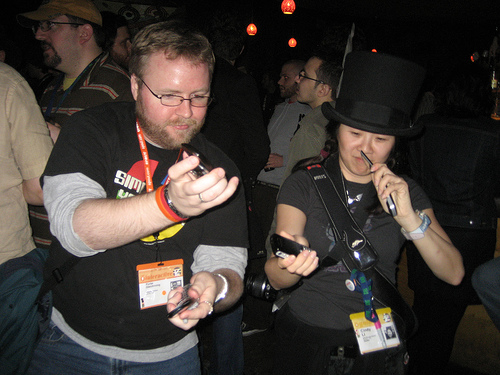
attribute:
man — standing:
[25, 18, 254, 375]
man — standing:
[23, 0, 137, 257]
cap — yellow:
[21, 1, 108, 34]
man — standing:
[279, 54, 343, 199]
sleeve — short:
[37, 111, 109, 191]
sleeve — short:
[198, 160, 252, 250]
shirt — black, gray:
[37, 96, 250, 367]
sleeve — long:
[190, 167, 252, 294]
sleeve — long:
[37, 120, 114, 265]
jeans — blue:
[22, 309, 201, 374]